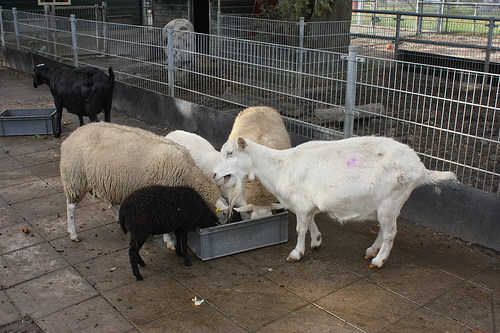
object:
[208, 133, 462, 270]
goat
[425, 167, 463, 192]
tail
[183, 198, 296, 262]
container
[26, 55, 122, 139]
goat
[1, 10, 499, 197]
fence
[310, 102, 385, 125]
log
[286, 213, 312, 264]
legs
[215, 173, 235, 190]
mouth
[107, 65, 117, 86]
tail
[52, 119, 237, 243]
goat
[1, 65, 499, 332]
floor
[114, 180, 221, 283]
goat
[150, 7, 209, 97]
cow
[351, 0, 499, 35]
area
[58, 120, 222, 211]
fur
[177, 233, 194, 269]
legs